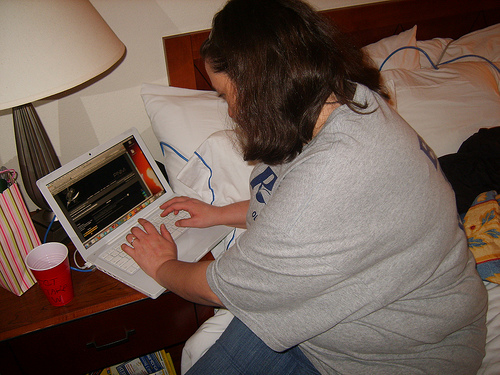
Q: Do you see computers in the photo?
A: Yes, there is a computer.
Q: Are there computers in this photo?
A: Yes, there is a computer.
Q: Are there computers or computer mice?
A: Yes, there is a computer.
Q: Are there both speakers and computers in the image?
A: No, there is a computer but no speakers.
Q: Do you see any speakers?
A: No, there are no speakers.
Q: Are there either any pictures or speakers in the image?
A: No, there are no speakers or pictures.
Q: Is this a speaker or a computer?
A: This is a computer.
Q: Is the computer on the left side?
A: Yes, the computer is on the left of the image.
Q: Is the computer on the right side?
A: No, the computer is on the left of the image.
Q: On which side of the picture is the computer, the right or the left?
A: The computer is on the left of the image.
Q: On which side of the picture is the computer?
A: The computer is on the left of the image.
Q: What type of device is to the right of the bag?
A: The device is a computer.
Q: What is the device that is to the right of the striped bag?
A: The device is a computer.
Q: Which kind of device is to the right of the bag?
A: The device is a computer.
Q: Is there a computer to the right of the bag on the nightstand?
A: Yes, there is a computer to the right of the bag.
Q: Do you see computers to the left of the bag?
A: No, the computer is to the right of the bag.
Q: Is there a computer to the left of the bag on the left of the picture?
A: No, the computer is to the right of the bag.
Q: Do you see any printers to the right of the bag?
A: No, there is a computer to the right of the bag.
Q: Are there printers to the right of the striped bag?
A: No, there is a computer to the right of the bag.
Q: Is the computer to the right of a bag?
A: Yes, the computer is to the right of a bag.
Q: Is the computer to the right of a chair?
A: No, the computer is to the right of a bag.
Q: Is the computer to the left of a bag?
A: No, the computer is to the right of a bag.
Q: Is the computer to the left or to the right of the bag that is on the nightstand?
A: The computer is to the right of the bag.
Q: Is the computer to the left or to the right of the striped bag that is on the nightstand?
A: The computer is to the right of the bag.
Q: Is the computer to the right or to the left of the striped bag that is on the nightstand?
A: The computer is to the right of the bag.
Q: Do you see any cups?
A: Yes, there is a cup.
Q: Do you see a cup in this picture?
A: Yes, there is a cup.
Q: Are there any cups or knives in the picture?
A: Yes, there is a cup.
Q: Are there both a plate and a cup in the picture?
A: No, there is a cup but no plates.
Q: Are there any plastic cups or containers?
A: Yes, there is a plastic cup.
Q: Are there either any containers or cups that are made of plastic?
A: Yes, the cup is made of plastic.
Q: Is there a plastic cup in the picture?
A: Yes, there is a cup that is made of plastic.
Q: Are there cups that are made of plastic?
A: Yes, there is a cup that is made of plastic.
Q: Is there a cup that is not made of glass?
A: Yes, there is a cup that is made of plastic.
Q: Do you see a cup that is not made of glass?
A: Yes, there is a cup that is made of plastic.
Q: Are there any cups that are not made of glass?
A: Yes, there is a cup that is made of plastic.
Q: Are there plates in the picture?
A: No, there are no plates.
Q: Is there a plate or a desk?
A: No, there are no plates or desks.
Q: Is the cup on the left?
A: Yes, the cup is on the left of the image.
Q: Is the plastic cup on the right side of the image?
A: No, the cup is on the left of the image.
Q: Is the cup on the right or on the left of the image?
A: The cup is on the left of the image.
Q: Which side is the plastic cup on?
A: The cup is on the left of the image.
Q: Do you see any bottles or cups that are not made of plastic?
A: No, there is a cup but it is made of plastic.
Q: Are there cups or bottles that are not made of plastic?
A: No, there is a cup but it is made of plastic.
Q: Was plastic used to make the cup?
A: Yes, the cup is made of plastic.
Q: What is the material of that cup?
A: The cup is made of plastic.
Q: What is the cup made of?
A: The cup is made of plastic.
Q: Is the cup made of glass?
A: No, the cup is made of plastic.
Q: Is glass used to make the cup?
A: No, the cup is made of plastic.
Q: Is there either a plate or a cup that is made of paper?
A: No, there is a cup but it is made of plastic.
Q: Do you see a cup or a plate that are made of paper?
A: No, there is a cup but it is made of plastic.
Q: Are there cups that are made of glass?
A: No, there is a cup but it is made of plastic.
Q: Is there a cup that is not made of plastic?
A: No, there is a cup but it is made of plastic.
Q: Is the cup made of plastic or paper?
A: The cup is made of plastic.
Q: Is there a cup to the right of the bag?
A: Yes, there is a cup to the right of the bag.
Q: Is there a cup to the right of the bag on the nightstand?
A: Yes, there is a cup to the right of the bag.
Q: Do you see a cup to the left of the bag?
A: No, the cup is to the right of the bag.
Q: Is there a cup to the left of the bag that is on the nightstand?
A: No, the cup is to the right of the bag.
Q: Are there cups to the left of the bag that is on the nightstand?
A: No, the cup is to the right of the bag.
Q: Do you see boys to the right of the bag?
A: No, there is a cup to the right of the bag.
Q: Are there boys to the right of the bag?
A: No, there is a cup to the right of the bag.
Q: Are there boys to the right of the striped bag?
A: No, there is a cup to the right of the bag.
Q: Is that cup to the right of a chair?
A: No, the cup is to the right of a bag.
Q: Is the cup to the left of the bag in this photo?
A: No, the cup is to the right of the bag.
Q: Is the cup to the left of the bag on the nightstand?
A: No, the cup is to the right of the bag.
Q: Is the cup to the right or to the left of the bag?
A: The cup is to the right of the bag.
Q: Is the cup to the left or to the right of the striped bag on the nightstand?
A: The cup is to the right of the bag.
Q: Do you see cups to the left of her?
A: Yes, there is a cup to the left of the lady.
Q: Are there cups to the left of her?
A: Yes, there is a cup to the left of the lady.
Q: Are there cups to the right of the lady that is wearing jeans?
A: No, the cup is to the left of the lady.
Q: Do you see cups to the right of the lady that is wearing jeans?
A: No, the cup is to the left of the lady.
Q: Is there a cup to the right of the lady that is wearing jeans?
A: No, the cup is to the left of the lady.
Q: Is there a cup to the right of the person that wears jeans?
A: No, the cup is to the left of the lady.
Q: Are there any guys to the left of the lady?
A: No, there is a cup to the left of the lady.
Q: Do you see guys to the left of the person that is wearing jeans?
A: No, there is a cup to the left of the lady.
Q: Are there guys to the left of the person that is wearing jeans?
A: No, there is a cup to the left of the lady.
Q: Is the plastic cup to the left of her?
A: Yes, the cup is to the left of a lady.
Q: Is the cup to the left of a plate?
A: No, the cup is to the left of a lady.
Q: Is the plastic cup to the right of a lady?
A: No, the cup is to the left of a lady.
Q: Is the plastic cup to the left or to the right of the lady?
A: The cup is to the left of the lady.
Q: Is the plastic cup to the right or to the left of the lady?
A: The cup is to the left of the lady.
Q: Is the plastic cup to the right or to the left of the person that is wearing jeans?
A: The cup is to the left of the lady.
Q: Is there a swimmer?
A: No, there are no swimmers.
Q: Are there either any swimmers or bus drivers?
A: No, there are no swimmers or bus drivers.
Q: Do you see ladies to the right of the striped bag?
A: Yes, there is a lady to the right of the bag.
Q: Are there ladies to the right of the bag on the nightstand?
A: Yes, there is a lady to the right of the bag.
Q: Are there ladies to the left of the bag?
A: No, the lady is to the right of the bag.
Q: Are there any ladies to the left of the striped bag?
A: No, the lady is to the right of the bag.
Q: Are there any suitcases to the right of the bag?
A: No, there is a lady to the right of the bag.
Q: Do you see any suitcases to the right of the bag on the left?
A: No, there is a lady to the right of the bag.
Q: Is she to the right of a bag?
A: Yes, the lady is to the right of a bag.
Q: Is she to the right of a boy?
A: No, the lady is to the right of a bag.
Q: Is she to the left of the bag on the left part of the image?
A: No, the lady is to the right of the bag.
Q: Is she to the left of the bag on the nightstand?
A: No, the lady is to the right of the bag.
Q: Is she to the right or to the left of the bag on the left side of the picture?
A: The lady is to the right of the bag.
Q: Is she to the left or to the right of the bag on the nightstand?
A: The lady is to the right of the bag.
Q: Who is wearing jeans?
A: The lady is wearing jeans.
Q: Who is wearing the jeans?
A: The lady is wearing jeans.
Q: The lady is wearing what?
A: The lady is wearing jeans.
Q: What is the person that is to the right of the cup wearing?
A: The lady is wearing jeans.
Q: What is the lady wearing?
A: The lady is wearing jeans.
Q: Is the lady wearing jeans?
A: Yes, the lady is wearing jeans.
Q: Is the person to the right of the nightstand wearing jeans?
A: Yes, the lady is wearing jeans.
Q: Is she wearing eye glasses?
A: No, the lady is wearing jeans.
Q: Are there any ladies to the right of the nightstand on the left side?
A: Yes, there is a lady to the right of the nightstand.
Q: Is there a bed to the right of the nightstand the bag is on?
A: No, there is a lady to the right of the nightstand.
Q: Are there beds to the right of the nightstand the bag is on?
A: No, there is a lady to the right of the nightstand.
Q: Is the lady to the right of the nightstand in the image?
A: Yes, the lady is to the right of the nightstand.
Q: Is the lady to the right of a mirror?
A: No, the lady is to the right of the nightstand.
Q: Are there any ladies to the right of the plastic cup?
A: Yes, there is a lady to the right of the cup.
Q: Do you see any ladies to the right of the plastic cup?
A: Yes, there is a lady to the right of the cup.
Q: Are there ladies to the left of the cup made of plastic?
A: No, the lady is to the right of the cup.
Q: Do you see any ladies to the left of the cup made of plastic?
A: No, the lady is to the right of the cup.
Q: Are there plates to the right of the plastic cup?
A: No, there is a lady to the right of the cup.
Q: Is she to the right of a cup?
A: Yes, the lady is to the right of a cup.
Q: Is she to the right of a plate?
A: No, the lady is to the right of a cup.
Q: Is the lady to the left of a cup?
A: No, the lady is to the right of a cup.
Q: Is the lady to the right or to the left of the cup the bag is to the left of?
A: The lady is to the right of the cup.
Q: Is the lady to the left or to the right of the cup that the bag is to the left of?
A: The lady is to the right of the cup.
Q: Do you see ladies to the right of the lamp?
A: Yes, there is a lady to the right of the lamp.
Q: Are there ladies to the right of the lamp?
A: Yes, there is a lady to the right of the lamp.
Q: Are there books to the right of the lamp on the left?
A: No, there is a lady to the right of the lamp.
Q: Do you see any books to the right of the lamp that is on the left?
A: No, there is a lady to the right of the lamp.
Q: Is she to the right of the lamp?
A: Yes, the lady is to the right of the lamp.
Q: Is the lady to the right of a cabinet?
A: No, the lady is to the right of the lamp.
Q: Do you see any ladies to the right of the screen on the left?
A: Yes, there is a lady to the right of the screen.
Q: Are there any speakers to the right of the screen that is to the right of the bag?
A: No, there is a lady to the right of the screen.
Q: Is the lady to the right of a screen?
A: Yes, the lady is to the right of a screen.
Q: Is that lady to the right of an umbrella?
A: No, the lady is to the right of a screen.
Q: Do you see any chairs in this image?
A: No, there are no chairs.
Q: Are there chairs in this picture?
A: No, there are no chairs.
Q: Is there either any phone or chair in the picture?
A: No, there are no chairs or phones.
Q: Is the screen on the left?
A: Yes, the screen is on the left of the image.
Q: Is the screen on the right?
A: No, the screen is on the left of the image.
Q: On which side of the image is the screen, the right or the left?
A: The screen is on the left of the image.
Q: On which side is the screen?
A: The screen is on the left of the image.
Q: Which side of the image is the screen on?
A: The screen is on the left of the image.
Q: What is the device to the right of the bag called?
A: The device is a screen.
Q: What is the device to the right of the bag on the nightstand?
A: The device is a screen.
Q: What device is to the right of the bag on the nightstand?
A: The device is a screen.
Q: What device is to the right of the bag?
A: The device is a screen.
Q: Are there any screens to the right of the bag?
A: Yes, there is a screen to the right of the bag.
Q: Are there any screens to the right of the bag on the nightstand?
A: Yes, there is a screen to the right of the bag.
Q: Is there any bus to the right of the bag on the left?
A: No, there is a screen to the right of the bag.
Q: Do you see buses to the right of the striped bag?
A: No, there is a screen to the right of the bag.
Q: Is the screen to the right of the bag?
A: Yes, the screen is to the right of the bag.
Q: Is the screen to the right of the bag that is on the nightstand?
A: Yes, the screen is to the right of the bag.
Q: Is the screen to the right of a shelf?
A: No, the screen is to the right of the bag.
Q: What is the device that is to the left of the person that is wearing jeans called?
A: The device is a screen.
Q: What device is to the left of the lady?
A: The device is a screen.